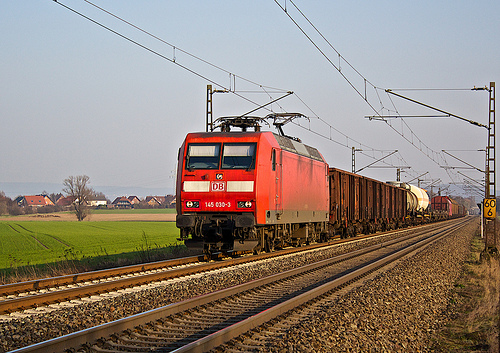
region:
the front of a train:
[173, 135, 260, 235]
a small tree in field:
[46, 173, 98, 233]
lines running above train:
[123, 45, 354, 117]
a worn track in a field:
[8, 218, 102, 262]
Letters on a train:
[211, 180, 225, 192]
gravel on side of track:
[323, 291, 402, 346]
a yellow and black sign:
[472, 196, 499, 226]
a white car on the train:
[402, 186, 436, 224]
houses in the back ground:
[15, 186, 184, 218]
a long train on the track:
[149, 119, 485, 289]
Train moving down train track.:
[166, 115, 443, 263]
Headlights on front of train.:
[183, 194, 255, 211]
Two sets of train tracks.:
[109, 262, 251, 344]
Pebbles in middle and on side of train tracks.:
[201, 275, 389, 309]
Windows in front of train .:
[183, 140, 259, 172]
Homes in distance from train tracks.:
[98, 185, 172, 212]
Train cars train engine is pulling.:
[335, 163, 460, 230]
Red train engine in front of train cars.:
[171, 122, 331, 254]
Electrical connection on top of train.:
[203, 80, 315, 133]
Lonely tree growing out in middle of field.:
[61, 171, 101, 223]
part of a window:
[231, 145, 248, 155]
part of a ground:
[394, 258, 420, 295]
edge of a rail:
[338, 271, 370, 301]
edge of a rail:
[308, 288, 330, 307]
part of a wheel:
[262, 227, 274, 243]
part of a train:
[222, 173, 264, 223]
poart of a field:
[93, 223, 124, 250]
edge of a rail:
[271, 288, 312, 328]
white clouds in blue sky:
[15, 29, 65, 73]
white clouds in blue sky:
[20, 103, 71, 144]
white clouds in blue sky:
[54, 58, 102, 83]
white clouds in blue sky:
[107, 78, 167, 133]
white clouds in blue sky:
[71, 122, 129, 163]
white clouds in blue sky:
[134, 73, 191, 127]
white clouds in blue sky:
[227, 25, 277, 66]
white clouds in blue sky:
[383, 12, 426, 57]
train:
[177, 121, 327, 234]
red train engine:
[174, 113, 339, 254]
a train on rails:
[171, 113, 487, 259]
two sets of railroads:
[9, 253, 297, 346]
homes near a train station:
[3, 174, 208, 263]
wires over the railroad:
[78, 6, 495, 263]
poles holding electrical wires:
[341, 58, 498, 195]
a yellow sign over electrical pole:
[478, 182, 498, 227]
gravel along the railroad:
[249, 216, 479, 351]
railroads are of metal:
[16, 253, 346, 350]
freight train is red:
[168, 118, 476, 255]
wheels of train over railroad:
[201, 225, 379, 267]